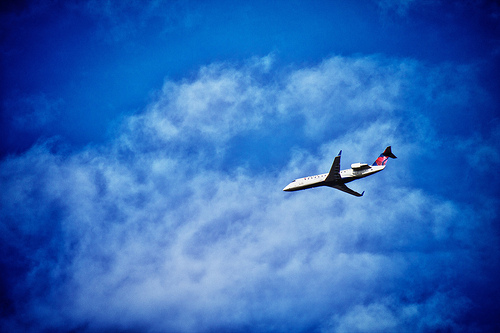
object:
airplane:
[281, 146, 398, 198]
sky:
[0, 1, 500, 333]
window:
[305, 176, 310, 181]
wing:
[324, 149, 342, 182]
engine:
[348, 162, 370, 170]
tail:
[371, 146, 397, 166]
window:
[301, 177, 305, 181]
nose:
[280, 185, 289, 192]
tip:
[334, 150, 343, 157]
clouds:
[73, 199, 492, 332]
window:
[314, 175, 320, 179]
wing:
[329, 183, 365, 197]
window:
[312, 176, 317, 179]